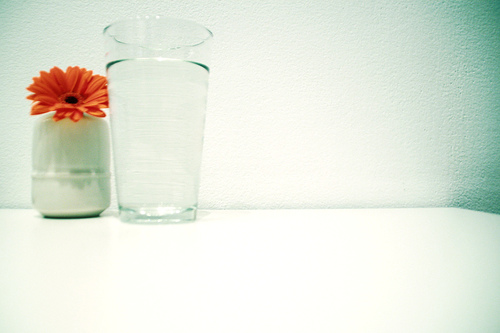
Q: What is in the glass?
A: There is water in the glass.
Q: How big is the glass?
A: The glass is big in size.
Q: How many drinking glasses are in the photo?
A: One.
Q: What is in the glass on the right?
A: Water.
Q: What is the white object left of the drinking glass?
A: Mini vase.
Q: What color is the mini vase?
A: White.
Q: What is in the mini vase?
A: One flower.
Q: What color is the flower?
A: Orange.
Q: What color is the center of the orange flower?
A: Brown.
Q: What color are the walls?
A: White.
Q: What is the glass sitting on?
A: Table.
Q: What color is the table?
A: White.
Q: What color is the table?
A: White.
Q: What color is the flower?
A: Orange.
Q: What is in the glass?
A: Water.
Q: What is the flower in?
A: A vase.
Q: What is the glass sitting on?
A: Table.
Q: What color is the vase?
A: White.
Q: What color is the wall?
A: White.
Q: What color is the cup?
A: Clear.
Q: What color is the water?
A: Clear.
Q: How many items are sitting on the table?
A: Two.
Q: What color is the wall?
A: White.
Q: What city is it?
A: Boston.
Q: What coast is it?
A: East Coast.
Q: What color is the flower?
A: Orange.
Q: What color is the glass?
A: Clear.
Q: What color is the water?
A: Clear.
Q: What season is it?
A: Autumn.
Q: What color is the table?
A: White.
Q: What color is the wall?
A: White.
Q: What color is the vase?
A: White.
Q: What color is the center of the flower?
A: Black.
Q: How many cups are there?
A: One.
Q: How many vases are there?
A: One.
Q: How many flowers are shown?
A: 1.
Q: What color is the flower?
A: Orange.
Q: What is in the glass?
A: Water.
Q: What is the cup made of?
A: Glass.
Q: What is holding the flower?
A: Vase.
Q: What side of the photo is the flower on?
A: Left.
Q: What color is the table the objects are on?
A: White.